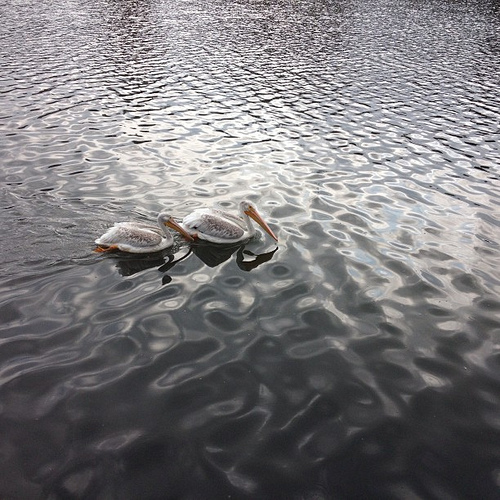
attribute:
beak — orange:
[251, 209, 281, 249]